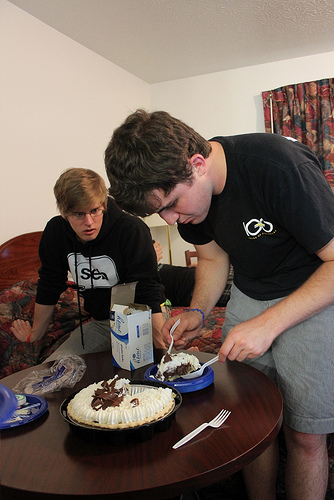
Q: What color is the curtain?
A: Red.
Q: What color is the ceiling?
A: White.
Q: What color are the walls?
A: White.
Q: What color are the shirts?
A: Black.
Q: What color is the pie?
A: White.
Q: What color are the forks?
A: White.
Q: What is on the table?
A: A cream pie.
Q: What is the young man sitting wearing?
A: Black and white jacket.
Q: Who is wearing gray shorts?
A: The young man bending.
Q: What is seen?
A: Edge of brown coffee table.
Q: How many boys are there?
A: Two.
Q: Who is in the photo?
A: Two males.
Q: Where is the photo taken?
A: In a room.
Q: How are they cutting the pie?
A: With plastic forks.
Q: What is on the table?
A: A pie.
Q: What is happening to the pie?
A: It's being sliced.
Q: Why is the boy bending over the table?
A: To get some pie.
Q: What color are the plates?
A: Blue.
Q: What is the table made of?
A: Wood.